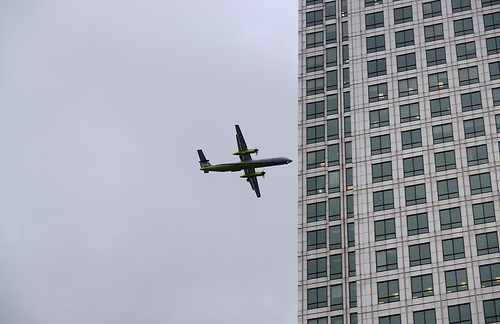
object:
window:
[306, 10, 323, 27]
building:
[298, 0, 499, 323]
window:
[306, 31, 327, 50]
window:
[306, 54, 325, 73]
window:
[306, 77, 326, 96]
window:
[306, 101, 324, 119]